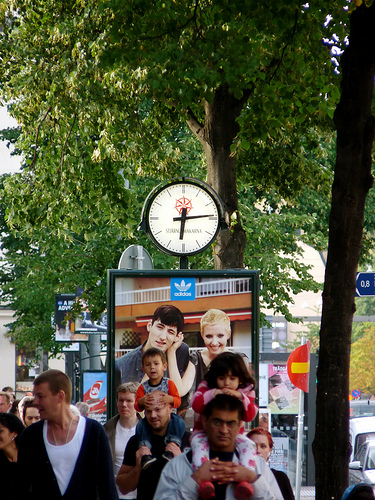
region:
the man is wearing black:
[0, 415, 123, 495]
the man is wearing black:
[30, 426, 91, 476]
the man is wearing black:
[46, 417, 103, 466]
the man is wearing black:
[38, 401, 120, 482]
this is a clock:
[147, 180, 228, 243]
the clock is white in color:
[162, 205, 170, 220]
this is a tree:
[83, 21, 289, 132]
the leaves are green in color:
[38, 186, 77, 227]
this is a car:
[354, 422, 373, 460]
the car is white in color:
[362, 418, 373, 428]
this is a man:
[27, 380, 99, 472]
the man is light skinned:
[43, 401, 56, 406]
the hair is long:
[231, 358, 243, 369]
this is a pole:
[88, 330, 103, 369]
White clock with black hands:
[145, 175, 226, 255]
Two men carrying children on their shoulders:
[109, 343, 293, 499]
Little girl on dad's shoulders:
[187, 354, 270, 494]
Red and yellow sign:
[280, 343, 317, 393]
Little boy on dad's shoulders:
[121, 349, 193, 479]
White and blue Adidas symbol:
[169, 277, 200, 305]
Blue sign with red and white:
[77, 368, 113, 434]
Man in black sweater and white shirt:
[7, 365, 123, 498]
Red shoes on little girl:
[190, 470, 270, 497]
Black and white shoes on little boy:
[140, 450, 180, 470]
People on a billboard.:
[109, 269, 256, 348]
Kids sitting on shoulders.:
[137, 349, 264, 497]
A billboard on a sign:
[78, 368, 108, 421]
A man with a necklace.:
[42, 417, 74, 449]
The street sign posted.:
[284, 336, 312, 393]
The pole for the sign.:
[295, 385, 303, 499]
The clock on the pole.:
[138, 171, 227, 269]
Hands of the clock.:
[173, 204, 213, 240]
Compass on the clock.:
[172, 195, 193, 215]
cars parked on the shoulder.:
[342, 398, 373, 484]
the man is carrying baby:
[146, 315, 267, 481]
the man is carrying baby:
[191, 360, 231, 456]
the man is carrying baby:
[183, 333, 249, 475]